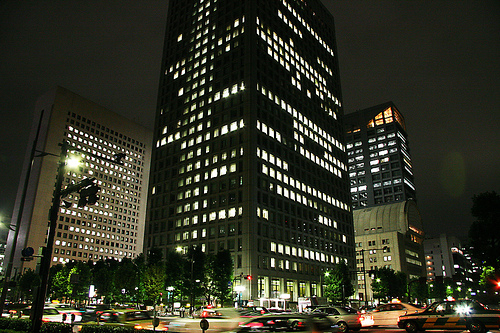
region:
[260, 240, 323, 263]
windows on a buliding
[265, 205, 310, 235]
windows on a building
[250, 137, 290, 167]
windows on a building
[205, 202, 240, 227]
windows on a building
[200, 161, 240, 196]
windows on a building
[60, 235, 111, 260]
windows on a buliding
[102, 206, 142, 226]
windows on a building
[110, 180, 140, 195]
windows on a building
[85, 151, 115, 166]
windows on a building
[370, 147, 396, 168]
windows on a buildings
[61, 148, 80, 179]
a light on a pole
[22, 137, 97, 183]
a light on a metal pole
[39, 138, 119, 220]
a pole with a light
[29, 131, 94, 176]
a metal pole with lgiht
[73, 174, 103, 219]
a traffic light on pole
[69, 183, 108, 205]
a traffic ligh ton a metal pole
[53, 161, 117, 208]
pole with a traffi clight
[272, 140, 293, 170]
window on a building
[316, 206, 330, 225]
window on a building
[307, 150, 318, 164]
A window on a building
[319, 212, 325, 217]
A window on a building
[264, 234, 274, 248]
A window on a building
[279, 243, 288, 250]
A window on a building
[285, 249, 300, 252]
A window on a building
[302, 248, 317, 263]
A window on a building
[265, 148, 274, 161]
A window on a building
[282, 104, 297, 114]
A window on a building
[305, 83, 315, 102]
A window on a building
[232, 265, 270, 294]
a traffic light on pole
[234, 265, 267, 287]
a traffic light on metal pole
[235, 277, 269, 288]
pole with traffic light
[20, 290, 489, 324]
several cars on the street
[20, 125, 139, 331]
a tall lamp post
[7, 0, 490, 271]
several tall buildings grouped together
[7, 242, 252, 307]
a row of green trees outside of a building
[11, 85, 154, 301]
a tall rectangular building with rows of windows